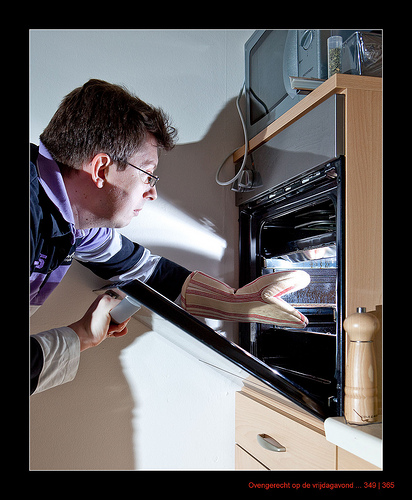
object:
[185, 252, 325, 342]
mitt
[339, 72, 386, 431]
panel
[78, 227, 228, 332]
arm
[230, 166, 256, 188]
dial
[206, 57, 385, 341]
microwave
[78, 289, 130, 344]
hand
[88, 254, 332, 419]
oven door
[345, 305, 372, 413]
grinder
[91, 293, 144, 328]
handle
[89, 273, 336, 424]
oven door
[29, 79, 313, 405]
man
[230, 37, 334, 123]
microwave open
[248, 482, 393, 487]
text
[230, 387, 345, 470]
door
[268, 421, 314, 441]
woodgrain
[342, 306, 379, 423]
pepper shaker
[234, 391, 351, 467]
drawer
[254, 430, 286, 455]
handle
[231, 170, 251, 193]
oven knobs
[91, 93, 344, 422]
oven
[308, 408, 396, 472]
counter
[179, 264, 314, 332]
oven mitt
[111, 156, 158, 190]
glasses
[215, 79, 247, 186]
cord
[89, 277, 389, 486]
door